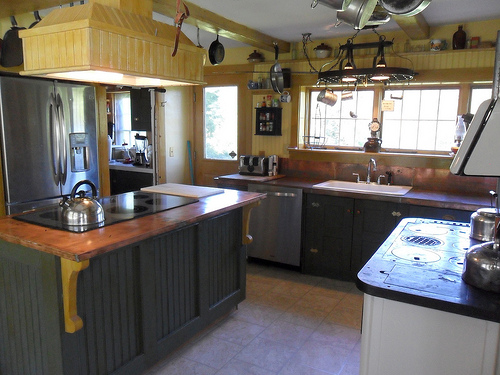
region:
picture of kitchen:
[46, 22, 464, 373]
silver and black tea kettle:
[47, 176, 104, 240]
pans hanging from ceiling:
[165, 33, 298, 94]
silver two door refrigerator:
[2, 81, 113, 208]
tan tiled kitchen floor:
[244, 290, 323, 367]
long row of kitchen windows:
[296, 61, 498, 157]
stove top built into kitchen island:
[32, 164, 184, 246]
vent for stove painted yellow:
[33, 5, 208, 107]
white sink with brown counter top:
[317, 164, 418, 200]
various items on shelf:
[398, 21, 493, 65]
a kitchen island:
[1, 180, 268, 374]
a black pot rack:
[315, 35, 418, 95]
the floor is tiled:
[140, 256, 365, 371]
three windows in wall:
[295, 80, 495, 155]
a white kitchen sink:
[310, 156, 411, 196]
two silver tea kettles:
[462, 188, 499, 295]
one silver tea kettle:
[55, 179, 107, 227]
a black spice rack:
[252, 104, 282, 137]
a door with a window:
[190, 72, 247, 189]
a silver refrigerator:
[2, 75, 102, 217]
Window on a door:
[201, 85, 236, 160]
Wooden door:
[195, 60, 250, 181]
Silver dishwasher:
[245, 177, 301, 263]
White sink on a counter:
[310, 175, 410, 192]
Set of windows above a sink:
[297, 80, 497, 155]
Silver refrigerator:
[0, 75, 102, 217]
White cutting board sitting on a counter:
[138, 181, 224, 198]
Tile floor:
[102, 260, 364, 373]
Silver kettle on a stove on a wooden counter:
[58, 178, 103, 233]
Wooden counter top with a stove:
[0, 187, 265, 260]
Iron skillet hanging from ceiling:
[206, 15, 243, 72]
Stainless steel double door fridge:
[0, 73, 107, 209]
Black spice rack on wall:
[250, 92, 285, 143]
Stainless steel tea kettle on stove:
[45, 176, 127, 239]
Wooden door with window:
[180, 68, 253, 198]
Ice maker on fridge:
[68, 125, 98, 176]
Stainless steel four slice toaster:
[231, 142, 291, 187]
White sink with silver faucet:
[305, 155, 412, 195]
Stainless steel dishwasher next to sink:
[242, 181, 309, 268]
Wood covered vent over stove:
[12, 20, 212, 91]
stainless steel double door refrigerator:
[0, 83, 100, 210]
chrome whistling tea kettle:
[55, 178, 108, 227]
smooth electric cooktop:
[7, 180, 202, 237]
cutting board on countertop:
[137, 172, 262, 212]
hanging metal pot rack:
[306, 25, 426, 117]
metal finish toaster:
[230, 143, 277, 174]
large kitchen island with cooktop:
[5, 160, 256, 370]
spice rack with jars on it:
[251, 93, 286, 139]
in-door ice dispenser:
[60, 122, 96, 180]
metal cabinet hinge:
[304, 196, 326, 214]